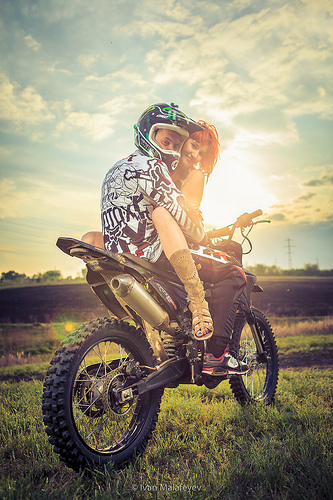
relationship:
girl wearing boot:
[80, 119, 220, 342] [167, 245, 214, 340]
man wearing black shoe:
[131, 96, 239, 376] [201, 349, 250, 379]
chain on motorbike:
[82, 363, 121, 376] [39, 208, 282, 480]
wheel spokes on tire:
[40, 315, 162, 477] [39, 317, 167, 475]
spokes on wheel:
[236, 318, 272, 397] [226, 309, 280, 412]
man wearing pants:
[98, 102, 250, 376] [119, 234, 258, 379]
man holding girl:
[98, 102, 250, 376] [80, 119, 220, 342]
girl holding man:
[80, 119, 220, 342] [98, 102, 250, 376]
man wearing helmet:
[98, 102, 250, 376] [132, 101, 205, 169]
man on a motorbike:
[98, 102, 250, 376] [39, 208, 280, 473]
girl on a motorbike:
[80, 119, 220, 342] [39, 208, 280, 473]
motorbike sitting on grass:
[22, 213, 327, 480] [0, 309, 331, 496]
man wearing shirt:
[98, 102, 250, 376] [101, 151, 205, 264]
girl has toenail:
[159, 119, 223, 282] [192, 325, 203, 335]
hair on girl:
[200, 119, 218, 177] [78, 119, 220, 341]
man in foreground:
[98, 102, 250, 376] [0, 102, 331, 497]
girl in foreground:
[80, 119, 220, 342] [0, 102, 331, 497]